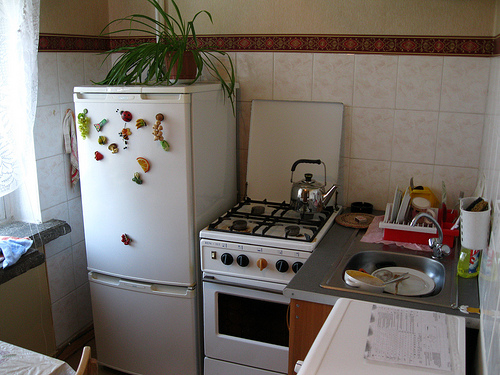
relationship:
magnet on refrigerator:
[121, 232, 134, 249] [72, 81, 239, 373]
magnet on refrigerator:
[136, 156, 152, 174] [72, 81, 239, 373]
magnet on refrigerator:
[94, 152, 105, 163] [72, 81, 239, 373]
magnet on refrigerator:
[135, 117, 150, 130] [72, 81, 239, 373]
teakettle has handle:
[290, 158, 339, 216] [290, 157, 329, 188]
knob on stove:
[220, 252, 235, 266] [200, 197, 345, 374]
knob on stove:
[236, 253, 252, 268] [200, 197, 345, 374]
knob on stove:
[256, 256, 269, 272] [200, 197, 345, 374]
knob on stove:
[274, 257, 291, 273] [200, 197, 345, 374]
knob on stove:
[291, 261, 305, 273] [200, 197, 345, 374]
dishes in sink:
[344, 266, 438, 296] [340, 247, 446, 298]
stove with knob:
[200, 197, 345, 374] [220, 252, 235, 266]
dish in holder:
[397, 186, 414, 225] [378, 203, 460, 249]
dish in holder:
[390, 187, 401, 226] [378, 203, 460, 249]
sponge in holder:
[466, 197, 489, 212] [457, 194, 493, 252]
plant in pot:
[94, 1, 243, 115] [162, 53, 196, 83]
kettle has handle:
[290, 158, 339, 216] [290, 157, 329, 188]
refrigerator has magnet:
[72, 81, 239, 373] [94, 152, 105, 163]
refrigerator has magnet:
[72, 81, 239, 373] [121, 232, 134, 249]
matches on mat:
[354, 213, 368, 224] [336, 210, 376, 229]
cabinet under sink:
[287, 298, 333, 374] [340, 247, 446, 298]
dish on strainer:
[397, 186, 414, 225] [378, 203, 460, 249]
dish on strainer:
[390, 187, 401, 226] [378, 203, 460, 249]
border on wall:
[112, 32, 500, 59] [110, 1, 497, 211]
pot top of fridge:
[162, 53, 196, 83] [72, 81, 239, 373]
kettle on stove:
[290, 158, 339, 216] [200, 197, 345, 374]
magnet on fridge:
[135, 117, 150, 130] [72, 81, 239, 373]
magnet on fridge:
[116, 109, 134, 124] [72, 81, 239, 373]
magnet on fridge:
[92, 117, 110, 132] [72, 81, 239, 373]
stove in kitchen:
[200, 197, 345, 374] [0, 1, 500, 374]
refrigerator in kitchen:
[72, 81, 239, 373] [0, 1, 500, 374]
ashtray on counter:
[350, 198, 373, 213] [283, 204, 482, 326]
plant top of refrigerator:
[94, 1, 243, 115] [72, 81, 239, 373]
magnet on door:
[136, 156, 152, 174] [72, 96, 198, 288]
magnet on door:
[121, 232, 134, 249] [72, 96, 198, 288]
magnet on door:
[116, 109, 134, 124] [72, 96, 198, 288]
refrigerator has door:
[72, 81, 239, 373] [72, 96, 198, 288]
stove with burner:
[200, 197, 345, 374] [209, 214, 263, 238]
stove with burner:
[200, 197, 345, 374] [262, 218, 320, 244]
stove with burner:
[200, 197, 345, 374] [232, 194, 281, 218]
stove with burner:
[200, 197, 345, 374] [278, 197, 333, 224]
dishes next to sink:
[389, 189, 413, 224] [340, 247, 446, 298]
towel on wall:
[60, 107, 78, 186] [22, 1, 110, 349]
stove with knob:
[200, 197, 345, 374] [236, 253, 252, 268]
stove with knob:
[200, 197, 345, 374] [274, 257, 291, 273]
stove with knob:
[200, 197, 345, 374] [291, 261, 305, 273]